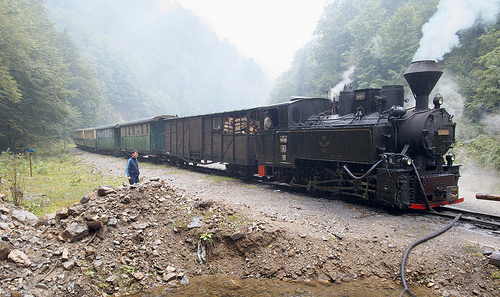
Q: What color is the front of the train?
A: Black.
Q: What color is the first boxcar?
A: Brown.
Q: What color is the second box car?
A: Green.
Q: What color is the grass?
A: Green.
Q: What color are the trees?
A: Green.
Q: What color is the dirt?
A: Brown.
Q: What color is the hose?
A: Black.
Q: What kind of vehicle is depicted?
A: Train.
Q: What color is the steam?
A: White.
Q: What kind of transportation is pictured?
A: Train.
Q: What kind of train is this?
A: Steam.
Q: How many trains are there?
A: 1.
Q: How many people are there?
A: 1.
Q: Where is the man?
A: Standing by the dirt pile.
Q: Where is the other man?
A: On the train engine.